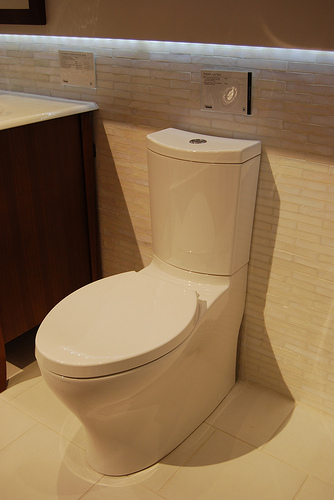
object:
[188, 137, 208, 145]
button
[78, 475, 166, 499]
tile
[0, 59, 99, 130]
counter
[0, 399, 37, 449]
tile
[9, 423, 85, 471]
tile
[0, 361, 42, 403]
tile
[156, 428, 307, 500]
tile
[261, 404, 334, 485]
tile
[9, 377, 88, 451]
tile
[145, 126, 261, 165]
lid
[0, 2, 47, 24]
frame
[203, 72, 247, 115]
sign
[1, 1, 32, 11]
picture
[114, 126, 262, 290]
sink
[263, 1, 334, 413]
wall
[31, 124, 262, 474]
toilet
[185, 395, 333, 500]
floor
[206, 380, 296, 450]
tile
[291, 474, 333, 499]
tile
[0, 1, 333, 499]
bathroom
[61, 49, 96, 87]
sign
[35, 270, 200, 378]
lid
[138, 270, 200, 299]
hinge